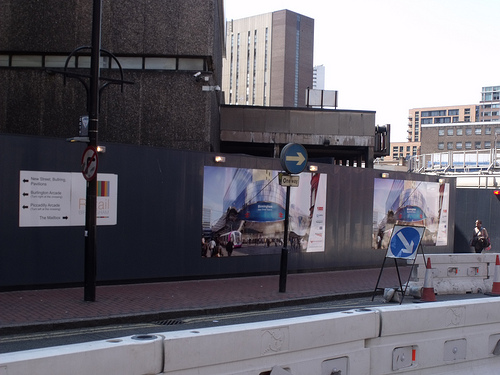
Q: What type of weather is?
A: It is clear.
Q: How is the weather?
A: It is clear.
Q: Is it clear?
A: Yes, it is clear.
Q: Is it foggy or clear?
A: It is clear.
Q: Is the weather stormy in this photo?
A: No, it is clear.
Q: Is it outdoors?
A: Yes, it is outdoors.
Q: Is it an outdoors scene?
A: Yes, it is outdoors.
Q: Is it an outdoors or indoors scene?
A: It is outdoors.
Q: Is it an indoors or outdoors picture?
A: It is outdoors.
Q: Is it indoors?
A: No, it is outdoors.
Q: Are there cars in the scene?
A: No, there are no cars.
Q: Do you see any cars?
A: No, there are no cars.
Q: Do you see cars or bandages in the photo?
A: No, there are no cars or bandages.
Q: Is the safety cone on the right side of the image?
A: Yes, the safety cone is on the right of the image.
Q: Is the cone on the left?
A: No, the cone is on the right of the image.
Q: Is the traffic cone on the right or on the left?
A: The traffic cone is on the right of the image.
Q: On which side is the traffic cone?
A: The traffic cone is on the right of the image.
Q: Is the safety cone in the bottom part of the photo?
A: Yes, the safety cone is in the bottom of the image.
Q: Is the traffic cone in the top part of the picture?
A: No, the traffic cone is in the bottom of the image.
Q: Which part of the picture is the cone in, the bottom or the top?
A: The cone is in the bottom of the image.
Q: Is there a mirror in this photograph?
A: No, there are no mirrors.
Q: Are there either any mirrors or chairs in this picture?
A: No, there are no mirrors or chairs.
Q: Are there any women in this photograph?
A: No, there are no women.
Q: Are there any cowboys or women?
A: No, there are no women or cowboys.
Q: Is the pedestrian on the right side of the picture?
A: Yes, the pedestrian is on the right of the image.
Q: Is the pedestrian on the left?
A: No, the pedestrian is on the right of the image.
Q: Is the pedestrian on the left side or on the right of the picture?
A: The pedestrian is on the right of the image.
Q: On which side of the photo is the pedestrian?
A: The pedestrian is on the right of the image.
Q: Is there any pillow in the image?
A: No, there are no pillows.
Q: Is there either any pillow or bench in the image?
A: No, there are no pillows or benches.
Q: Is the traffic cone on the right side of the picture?
A: Yes, the traffic cone is on the right of the image.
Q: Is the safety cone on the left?
A: No, the safety cone is on the right of the image.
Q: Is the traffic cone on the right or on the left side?
A: The traffic cone is on the right of the image.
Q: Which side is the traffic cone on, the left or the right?
A: The traffic cone is on the right of the image.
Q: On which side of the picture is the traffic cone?
A: The traffic cone is on the right of the image.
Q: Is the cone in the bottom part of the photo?
A: Yes, the cone is in the bottom of the image.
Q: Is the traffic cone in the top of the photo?
A: No, the traffic cone is in the bottom of the image.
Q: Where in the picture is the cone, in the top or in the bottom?
A: The cone is in the bottom of the image.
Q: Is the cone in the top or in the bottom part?
A: The cone is in the bottom of the image.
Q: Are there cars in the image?
A: No, there are no cars.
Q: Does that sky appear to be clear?
A: Yes, the sky is clear.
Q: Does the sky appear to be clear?
A: Yes, the sky is clear.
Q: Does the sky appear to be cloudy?
A: No, the sky is clear.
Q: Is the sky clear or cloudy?
A: The sky is clear.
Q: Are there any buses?
A: No, there are no buses.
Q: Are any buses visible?
A: No, there are no buses.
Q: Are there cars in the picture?
A: No, there are no cars.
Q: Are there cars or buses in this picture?
A: No, there are no cars or buses.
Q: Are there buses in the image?
A: No, there are no buses.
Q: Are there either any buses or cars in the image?
A: No, there are no buses or cars.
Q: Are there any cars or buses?
A: No, there are no buses or cars.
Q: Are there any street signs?
A: Yes, there is a street sign.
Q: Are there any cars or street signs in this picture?
A: Yes, there is a street sign.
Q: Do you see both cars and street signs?
A: No, there is a street sign but no cars.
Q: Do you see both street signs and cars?
A: No, there is a street sign but no cars.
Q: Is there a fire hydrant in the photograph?
A: No, there are no fire hydrants.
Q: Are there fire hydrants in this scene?
A: No, there are no fire hydrants.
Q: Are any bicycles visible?
A: No, there are no bicycles.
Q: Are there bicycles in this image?
A: No, there are no bicycles.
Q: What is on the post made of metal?
A: The sign is on the post.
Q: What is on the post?
A: The sign is on the post.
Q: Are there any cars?
A: No, there are no cars.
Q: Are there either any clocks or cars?
A: No, there are no cars or clocks.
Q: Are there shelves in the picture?
A: No, there are no shelves.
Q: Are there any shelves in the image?
A: No, there are no shelves.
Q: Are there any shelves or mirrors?
A: No, there are no shelves or mirrors.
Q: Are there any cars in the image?
A: No, there are no cars.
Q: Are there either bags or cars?
A: No, there are no cars or bags.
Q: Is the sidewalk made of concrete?
A: No, the sidewalk is made of cobblestone.